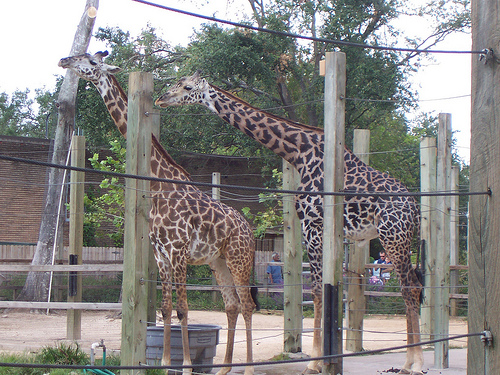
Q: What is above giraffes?
A: Sunny sky.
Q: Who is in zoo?
A: 2 giraffes.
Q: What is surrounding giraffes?
A: Fence.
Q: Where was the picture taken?
A: In zoo.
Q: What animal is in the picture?
A: A giraffe.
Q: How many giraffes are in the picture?
A: 2.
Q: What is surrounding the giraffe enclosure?
A: A fence.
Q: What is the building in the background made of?
A: Brick.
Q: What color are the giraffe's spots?
A: Brown.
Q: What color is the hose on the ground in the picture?
A: Green.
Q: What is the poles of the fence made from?
A: Wood.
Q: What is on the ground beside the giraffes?
A: A bucket.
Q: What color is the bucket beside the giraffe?
A: Gray.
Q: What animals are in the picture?
A: Giraffes.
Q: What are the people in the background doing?
A: Watching the giraffes.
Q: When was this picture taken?
A: Daytime.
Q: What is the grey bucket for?
A: Drinking water.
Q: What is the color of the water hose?
A: Green.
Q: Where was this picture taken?
A: A zoo.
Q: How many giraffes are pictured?
A: Two.